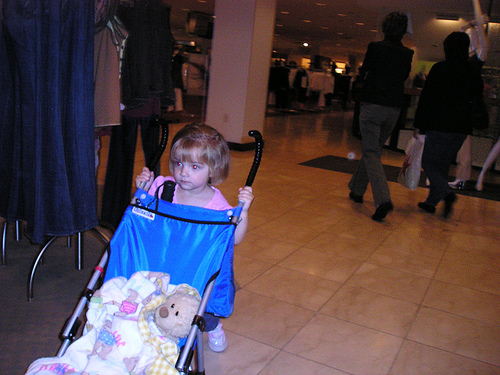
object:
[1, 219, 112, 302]
rack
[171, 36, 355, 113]
outlet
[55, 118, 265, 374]
stroller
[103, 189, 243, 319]
harness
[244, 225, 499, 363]
tiles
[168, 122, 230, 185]
hair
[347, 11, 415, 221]
woman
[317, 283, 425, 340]
tile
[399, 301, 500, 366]
floor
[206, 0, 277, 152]
pillar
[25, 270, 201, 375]
baby blankets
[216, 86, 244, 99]
wall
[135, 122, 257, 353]
child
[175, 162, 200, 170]
eyes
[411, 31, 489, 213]
people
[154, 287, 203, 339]
animal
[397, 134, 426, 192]
bag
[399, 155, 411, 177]
star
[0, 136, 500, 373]
ground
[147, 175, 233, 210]
shirt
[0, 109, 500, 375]
walkway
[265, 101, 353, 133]
center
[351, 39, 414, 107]
jacket